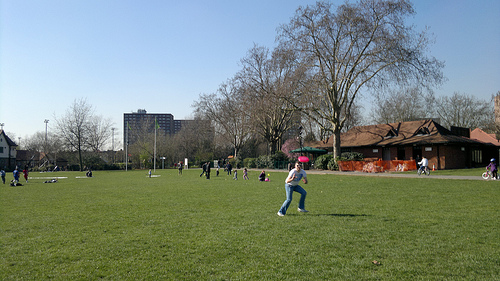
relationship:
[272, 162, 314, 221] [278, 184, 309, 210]
man wears jeans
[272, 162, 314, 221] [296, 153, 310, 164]
man awaits frisbee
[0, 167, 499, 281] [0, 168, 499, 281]
field of field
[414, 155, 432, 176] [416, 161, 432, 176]
person rides bicycles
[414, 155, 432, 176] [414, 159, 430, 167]
person wears shirt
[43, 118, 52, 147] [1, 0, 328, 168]
light pole in distance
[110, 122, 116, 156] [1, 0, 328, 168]
light pole in distance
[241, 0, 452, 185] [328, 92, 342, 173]
tree has trunk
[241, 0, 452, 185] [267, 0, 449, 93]
tree has sparse leaves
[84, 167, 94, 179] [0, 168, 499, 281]
person sitting on field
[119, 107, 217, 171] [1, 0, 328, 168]
building in distance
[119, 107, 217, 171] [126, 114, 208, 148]
building has many windows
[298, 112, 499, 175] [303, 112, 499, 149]
building has roof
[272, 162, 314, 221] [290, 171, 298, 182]
man has hand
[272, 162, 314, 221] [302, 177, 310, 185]
man has hand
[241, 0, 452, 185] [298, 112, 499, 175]
tree beside building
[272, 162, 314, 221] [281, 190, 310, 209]
man has legs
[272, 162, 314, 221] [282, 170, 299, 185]
man has arm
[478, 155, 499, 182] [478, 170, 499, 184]
child has bicycle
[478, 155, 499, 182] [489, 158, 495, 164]
child has bicycle helmet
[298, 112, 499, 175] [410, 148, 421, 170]
building has door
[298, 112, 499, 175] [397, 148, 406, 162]
building has door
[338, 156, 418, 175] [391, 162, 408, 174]
fence has tag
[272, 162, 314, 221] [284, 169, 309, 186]
man wears shirt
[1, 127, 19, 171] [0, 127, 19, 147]
building has roof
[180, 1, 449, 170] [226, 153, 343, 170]
trees in row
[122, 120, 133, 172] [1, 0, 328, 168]
flagpole in distance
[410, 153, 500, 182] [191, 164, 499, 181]
bicycles on sidewalk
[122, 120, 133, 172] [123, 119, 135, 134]
flagpole has flag